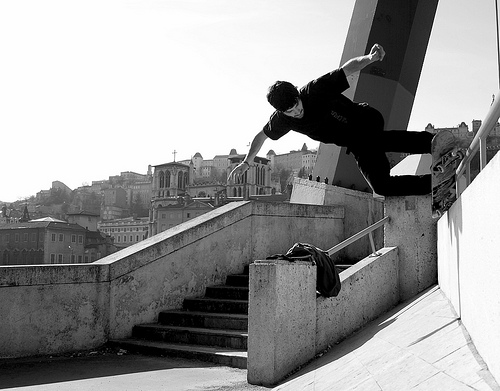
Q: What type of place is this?
A: It is a city.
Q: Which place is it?
A: It is a city.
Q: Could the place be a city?
A: Yes, it is a city.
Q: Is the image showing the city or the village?
A: It is showing the city.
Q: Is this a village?
A: No, it is a city.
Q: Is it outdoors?
A: Yes, it is outdoors.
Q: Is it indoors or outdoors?
A: It is outdoors.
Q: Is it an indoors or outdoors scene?
A: It is outdoors.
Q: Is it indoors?
A: No, it is outdoors.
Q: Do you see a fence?
A: No, there are no fences.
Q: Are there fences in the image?
A: No, there are no fences.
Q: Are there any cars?
A: No, there are no cars.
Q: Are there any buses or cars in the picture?
A: No, there are no cars or buses.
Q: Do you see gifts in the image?
A: No, there are no gifts.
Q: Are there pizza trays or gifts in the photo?
A: No, there are no gifts or pizza trays.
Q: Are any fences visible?
A: No, there are no fences.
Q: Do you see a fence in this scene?
A: No, there are no fences.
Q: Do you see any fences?
A: No, there are no fences.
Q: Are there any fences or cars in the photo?
A: No, there are no fences or cars.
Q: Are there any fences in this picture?
A: No, there are no fences.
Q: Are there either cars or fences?
A: No, there are no fences or cars.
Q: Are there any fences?
A: No, there are no fences.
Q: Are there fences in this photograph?
A: No, there are no fences.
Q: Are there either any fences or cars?
A: No, there are no fences or cars.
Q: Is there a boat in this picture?
A: No, there are no boats.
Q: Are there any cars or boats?
A: No, there are no boats or cars.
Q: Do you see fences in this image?
A: No, there are no fences.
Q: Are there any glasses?
A: No, there are no glasses.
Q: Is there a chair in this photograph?
A: No, there are no chairs.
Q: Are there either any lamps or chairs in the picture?
A: No, there are no chairs or lamps.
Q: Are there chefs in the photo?
A: No, there are no chefs.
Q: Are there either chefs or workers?
A: No, there are no chefs or workers.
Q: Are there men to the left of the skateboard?
A: Yes, there is a man to the left of the skateboard.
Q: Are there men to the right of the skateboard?
A: No, the man is to the left of the skateboard.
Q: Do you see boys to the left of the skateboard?
A: No, there is a man to the left of the skateboard.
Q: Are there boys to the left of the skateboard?
A: No, there is a man to the left of the skateboard.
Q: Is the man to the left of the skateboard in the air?
A: Yes, the man is to the left of the skateboard.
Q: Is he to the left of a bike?
A: No, the man is to the left of the skateboard.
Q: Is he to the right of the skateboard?
A: No, the man is to the left of the skateboard.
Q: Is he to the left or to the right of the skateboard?
A: The man is to the left of the skateboard.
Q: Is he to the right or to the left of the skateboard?
A: The man is to the left of the skateboard.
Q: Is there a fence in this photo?
A: No, there are no fences.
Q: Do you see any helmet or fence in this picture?
A: No, there are no fences or helmets.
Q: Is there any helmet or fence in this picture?
A: No, there are no fences or helmets.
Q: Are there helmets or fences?
A: No, there are no fences or helmets.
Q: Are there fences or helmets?
A: No, there are no fences or helmets.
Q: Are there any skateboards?
A: Yes, there is a skateboard.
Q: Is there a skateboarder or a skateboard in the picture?
A: Yes, there is a skateboard.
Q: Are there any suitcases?
A: No, there are no suitcases.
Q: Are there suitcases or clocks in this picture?
A: No, there are no suitcases or clocks.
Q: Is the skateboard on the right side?
A: Yes, the skateboard is on the right of the image.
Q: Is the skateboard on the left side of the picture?
A: No, the skateboard is on the right of the image.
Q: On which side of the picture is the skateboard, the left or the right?
A: The skateboard is on the right of the image.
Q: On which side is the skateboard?
A: The skateboard is on the right of the image.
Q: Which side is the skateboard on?
A: The skateboard is on the right of the image.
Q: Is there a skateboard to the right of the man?
A: Yes, there is a skateboard to the right of the man.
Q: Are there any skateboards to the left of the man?
A: No, the skateboard is to the right of the man.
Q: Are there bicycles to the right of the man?
A: No, there is a skateboard to the right of the man.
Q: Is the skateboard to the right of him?
A: Yes, the skateboard is to the right of the man.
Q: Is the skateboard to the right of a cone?
A: No, the skateboard is to the right of the man.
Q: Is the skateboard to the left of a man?
A: No, the skateboard is to the right of a man.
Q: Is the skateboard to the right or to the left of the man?
A: The skateboard is to the right of the man.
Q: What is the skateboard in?
A: The skateboard is in the air.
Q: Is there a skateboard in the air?
A: Yes, there is a skateboard in the air.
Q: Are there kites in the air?
A: No, there is a skateboard in the air.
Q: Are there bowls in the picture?
A: No, there are no bowls.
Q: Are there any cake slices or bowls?
A: No, there are no bowls or cake slices.